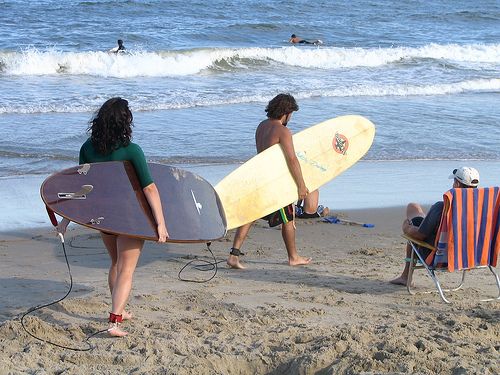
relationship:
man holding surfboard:
[226, 90, 313, 275] [213, 112, 375, 229]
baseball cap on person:
[444, 164, 479, 186] [402, 162, 487, 242]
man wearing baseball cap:
[391, 164, 478, 288] [448, 167, 481, 188]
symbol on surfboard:
[334, 130, 350, 157] [213, 112, 375, 229]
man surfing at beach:
[288, 33, 322, 46] [147, 296, 497, 371]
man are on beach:
[226, 92, 313, 270] [4, 58, 497, 373]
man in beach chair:
[388, 166, 480, 287] [398, 186, 498, 306]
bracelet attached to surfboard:
[14, 209, 126, 356] [35, 154, 232, 249]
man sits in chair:
[391, 164, 478, 288] [405, 183, 499, 310]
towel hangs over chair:
[446, 187, 498, 271] [401, 186, 498, 306]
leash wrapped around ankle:
[21, 231, 123, 350] [94, 301, 135, 351]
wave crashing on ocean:
[0, 42, 497, 80] [0, 1, 498, 100]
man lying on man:
[288, 34, 322, 46] [288, 33, 322, 46]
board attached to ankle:
[32, 164, 229, 241] [102, 308, 132, 339]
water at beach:
[37, 15, 460, 230] [48, 123, 498, 373]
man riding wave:
[288, 33, 322, 46] [0, 42, 497, 80]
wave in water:
[0, 42, 497, 80] [1, 0, 499, 179]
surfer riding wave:
[111, 39, 129, 55] [0, 42, 497, 80]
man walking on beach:
[226, 90, 313, 275] [10, 153, 490, 372]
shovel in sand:
[323, 202, 354, 236] [2, 160, 496, 372]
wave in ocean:
[0, 42, 500, 80] [26, 14, 467, 203]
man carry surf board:
[226, 90, 313, 275] [210, 111, 380, 233]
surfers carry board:
[78, 96, 170, 337] [39, 160, 228, 243]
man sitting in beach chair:
[388, 166, 480, 287] [392, 133, 499, 328]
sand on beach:
[1, 202, 497, 372] [10, 153, 490, 372]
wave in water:
[0, 42, 500, 80] [2, 2, 496, 162]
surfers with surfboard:
[78, 96, 170, 337] [40, 161, 227, 244]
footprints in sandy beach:
[4, 290, 499, 373] [0, 166, 497, 372]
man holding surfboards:
[226, 92, 313, 270] [216, 112, 371, 205]